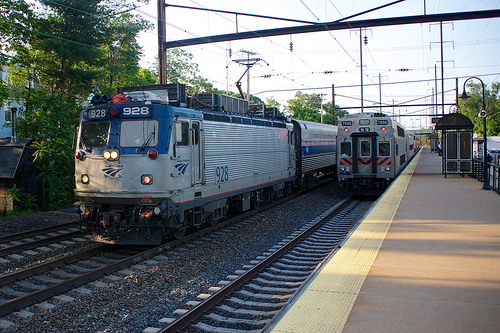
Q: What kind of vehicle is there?
A: Train.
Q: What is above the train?
A: Poles and wires.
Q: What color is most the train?
A: Silver.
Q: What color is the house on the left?
A: Blue.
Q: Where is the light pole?
A: On the walk way.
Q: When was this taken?
A: During the day.